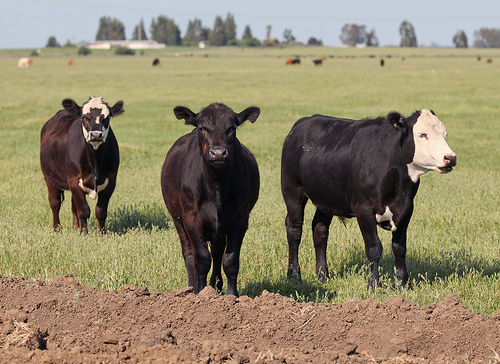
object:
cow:
[38, 95, 125, 235]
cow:
[159, 101, 262, 297]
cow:
[280, 107, 457, 293]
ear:
[173, 103, 198, 127]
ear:
[236, 105, 260, 124]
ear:
[60, 97, 82, 117]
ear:
[109, 99, 125, 116]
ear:
[385, 111, 407, 132]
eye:
[198, 127, 206, 136]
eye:
[226, 126, 237, 135]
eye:
[418, 133, 429, 141]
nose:
[89, 131, 106, 142]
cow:
[151, 57, 161, 66]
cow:
[285, 55, 301, 66]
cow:
[17, 57, 33, 68]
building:
[83, 39, 165, 51]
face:
[81, 100, 110, 144]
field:
[0, 0, 499, 364]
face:
[416, 110, 457, 175]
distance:
[0, 18, 499, 76]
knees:
[76, 205, 107, 219]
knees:
[196, 250, 239, 273]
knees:
[365, 240, 405, 263]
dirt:
[2, 272, 499, 363]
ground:
[2, 46, 499, 364]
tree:
[397, 19, 417, 49]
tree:
[340, 23, 367, 47]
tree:
[223, 11, 236, 45]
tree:
[208, 15, 229, 47]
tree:
[450, 29, 470, 50]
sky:
[0, 0, 497, 47]